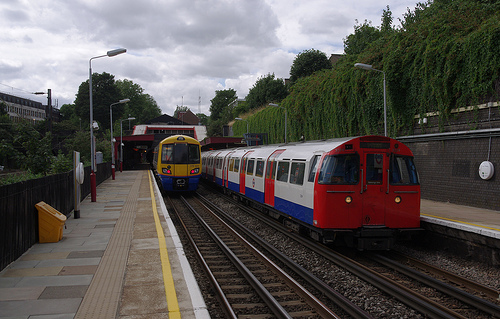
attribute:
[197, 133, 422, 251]
train — red, blue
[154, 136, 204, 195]
train — yellow, blue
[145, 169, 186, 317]
line — yellow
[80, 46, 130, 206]
light — curved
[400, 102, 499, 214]
wall — brick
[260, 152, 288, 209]
door — red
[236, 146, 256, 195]
door — red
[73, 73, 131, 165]
tree — green